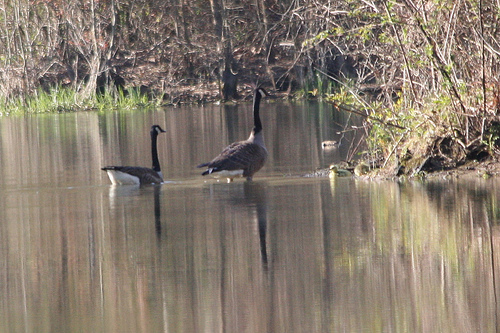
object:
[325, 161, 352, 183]
duck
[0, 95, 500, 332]
still water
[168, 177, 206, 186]
little ripples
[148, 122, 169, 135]
head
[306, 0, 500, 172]
plant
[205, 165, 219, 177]
feather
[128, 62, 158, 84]
fallen leaves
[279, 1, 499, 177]
brush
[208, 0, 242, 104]
tree trunk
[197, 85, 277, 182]
animal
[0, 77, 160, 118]
grass patch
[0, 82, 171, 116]
grass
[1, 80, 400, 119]
shore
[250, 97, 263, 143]
neck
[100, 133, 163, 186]
body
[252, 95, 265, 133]
long neck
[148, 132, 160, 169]
long neck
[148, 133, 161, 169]
neck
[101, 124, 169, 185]
animal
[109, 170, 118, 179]
feather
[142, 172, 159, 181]
feather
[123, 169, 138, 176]
feather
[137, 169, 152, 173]
feather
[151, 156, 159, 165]
feather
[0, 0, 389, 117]
bank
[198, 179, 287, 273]
reflections